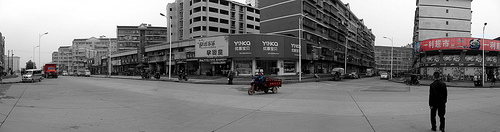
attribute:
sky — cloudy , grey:
[3, 5, 498, 68]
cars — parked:
[43, 54, 106, 83]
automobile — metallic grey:
[16, 64, 46, 85]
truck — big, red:
[40, 58, 63, 80]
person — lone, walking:
[419, 63, 459, 129]